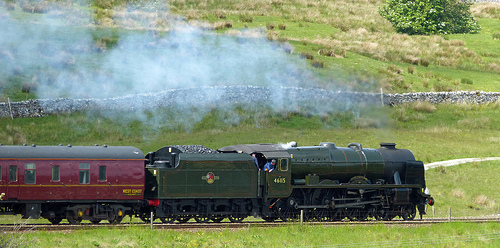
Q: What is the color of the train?
A: Red and black.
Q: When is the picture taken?
A: Daytime.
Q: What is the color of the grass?
A: Green.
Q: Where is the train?
A: In the track.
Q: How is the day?
A: Sunny.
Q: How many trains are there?
A: 1.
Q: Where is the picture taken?
A: Train track.